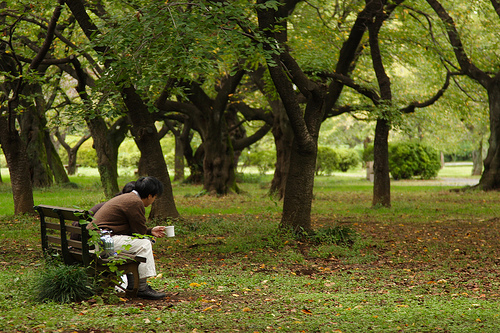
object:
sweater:
[83, 190, 150, 232]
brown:
[125, 206, 140, 232]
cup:
[157, 217, 182, 244]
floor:
[0, 132, 497, 332]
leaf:
[437, 278, 446, 283]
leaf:
[401, 267, 412, 272]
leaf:
[452, 247, 461, 252]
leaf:
[408, 257, 413, 262]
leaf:
[422, 245, 427, 251]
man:
[104, 156, 189, 261]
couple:
[69, 174, 167, 299]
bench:
[32, 202, 147, 297]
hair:
[136, 174, 163, 199]